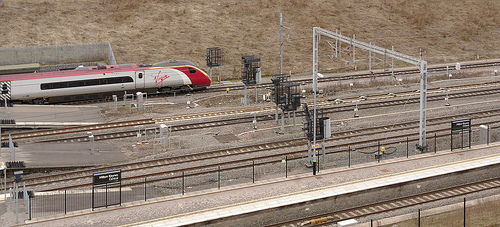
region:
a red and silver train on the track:
[4, 65, 226, 93]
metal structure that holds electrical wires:
[301, 23, 431, 152]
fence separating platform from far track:
[26, 134, 499, 204]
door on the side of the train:
[132, 69, 146, 89]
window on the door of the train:
[138, 73, 143, 80]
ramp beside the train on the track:
[2, 104, 103, 122]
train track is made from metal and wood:
[151, 100, 318, 134]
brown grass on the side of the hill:
[2, 3, 477, 58]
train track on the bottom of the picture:
[295, 176, 497, 222]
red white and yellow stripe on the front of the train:
[165, 63, 211, 84]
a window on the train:
[123, 73, 136, 85]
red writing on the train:
[150, 64, 173, 89]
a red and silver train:
[0, 60, 218, 111]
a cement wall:
[0, 37, 120, 71]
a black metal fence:
[20, 120, 497, 223]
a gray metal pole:
[417, 56, 430, 147]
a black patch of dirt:
[1, 0, 498, 81]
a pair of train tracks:
[266, 173, 499, 225]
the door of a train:
[132, 67, 148, 90]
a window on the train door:
[136, 70, 145, 79]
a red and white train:
[1, 54, 213, 101]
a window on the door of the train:
[135, 68, 145, 80]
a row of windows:
[33, 72, 136, 96]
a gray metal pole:
[412, 52, 438, 149]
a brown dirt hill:
[0, 0, 497, 80]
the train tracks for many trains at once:
[6, 60, 499, 217]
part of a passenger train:
[3, 62, 213, 100]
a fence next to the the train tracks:
[19, 129, 494, 218]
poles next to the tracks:
[200, 41, 328, 143]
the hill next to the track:
[4, 6, 485, 70]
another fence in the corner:
[366, 190, 499, 222]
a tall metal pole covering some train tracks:
[299, 25, 433, 145]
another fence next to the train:
[1, 39, 120, 69]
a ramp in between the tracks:
[6, 140, 123, 163]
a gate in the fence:
[94, 176, 121, 209]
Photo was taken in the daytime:
[3, 6, 496, 218]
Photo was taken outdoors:
[5, 3, 488, 216]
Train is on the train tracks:
[4, 40, 249, 118]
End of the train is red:
[175, 40, 218, 96]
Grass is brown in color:
[8, 4, 496, 42]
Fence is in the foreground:
[33, 163, 498, 216]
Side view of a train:
[0, 47, 233, 117]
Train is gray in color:
[3, 58, 220, 113]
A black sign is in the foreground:
[86, 166, 132, 194]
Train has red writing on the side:
[147, 68, 176, 93]